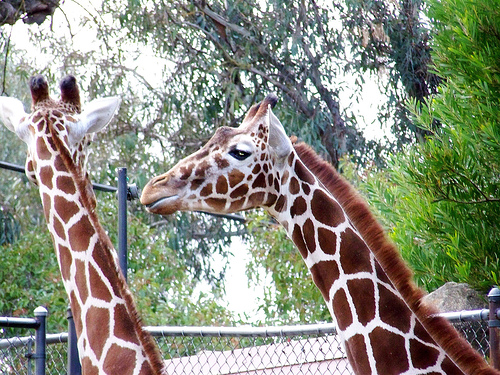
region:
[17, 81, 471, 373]
There are two giraffes.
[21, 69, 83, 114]
Knobs on top of the head.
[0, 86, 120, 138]
Back of the ears are white.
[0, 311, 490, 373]
Fence in front of the giraffe.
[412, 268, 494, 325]
Rock outside of the fence.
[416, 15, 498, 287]
Tree outside of the fence.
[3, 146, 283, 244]
Bar outside of the fence.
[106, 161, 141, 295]
Pole outside of the fence.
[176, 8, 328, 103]
The branches are brownish grey.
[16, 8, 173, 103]
The sky is white.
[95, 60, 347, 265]
the head of a giraffe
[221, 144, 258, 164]
the eye of a giraffe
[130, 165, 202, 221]
the nose of a giraffe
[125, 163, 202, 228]
the mouth of a giraffe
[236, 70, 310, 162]
the ear of a giraffe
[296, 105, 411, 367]
the neck of a giraffe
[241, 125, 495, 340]
the main of a giraffe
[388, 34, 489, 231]
the green leaves on a tree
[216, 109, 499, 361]
a giraffe near a fence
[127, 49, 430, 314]
a brown spotted giraffe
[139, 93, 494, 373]
A brown and white giraffe.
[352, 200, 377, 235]
The brown mane on the giraffe.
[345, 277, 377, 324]
A brown spot on the giraffe's neck.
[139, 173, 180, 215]
The mouth of the giraffe.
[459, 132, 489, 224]
Part of a green tree.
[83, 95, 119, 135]
The ear of the giraffe.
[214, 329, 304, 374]
Part of a chainlink fence.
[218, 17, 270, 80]
Part of some tree branches.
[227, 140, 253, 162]
The eye of the giraffe.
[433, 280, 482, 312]
Part of a rock.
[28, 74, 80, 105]
male giraffe ossicones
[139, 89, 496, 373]
brown and white Giraffa camelopardalis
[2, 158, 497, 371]
giraffe compound chain link fence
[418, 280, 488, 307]
gray rock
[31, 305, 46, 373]
vertical chainlink fence support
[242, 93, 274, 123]
horn-like giraffe ossicones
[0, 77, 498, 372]
two giraffes in zoo compound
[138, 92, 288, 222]
giraffe head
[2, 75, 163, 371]
giraffe with ears stuck out to the sides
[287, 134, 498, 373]
short bristly brown giraffe mane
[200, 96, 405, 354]
tall giraffe in zoo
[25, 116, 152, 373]
tall giraffe in zoo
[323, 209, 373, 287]
brown spots on giraffe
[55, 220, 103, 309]
brown spots on giraffe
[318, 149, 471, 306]
red mane on giraffe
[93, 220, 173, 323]
red mane on giraffe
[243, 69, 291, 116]
small horns on giraffe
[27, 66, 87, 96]
small horns on giraffe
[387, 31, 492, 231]
green plants on right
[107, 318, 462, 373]
chain link fence by giraffes